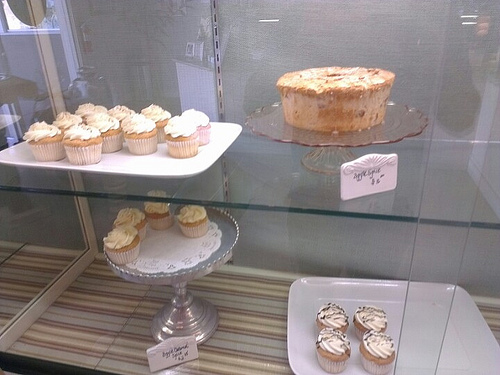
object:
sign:
[335, 157, 401, 200]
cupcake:
[163, 121, 198, 153]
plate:
[106, 154, 194, 179]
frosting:
[67, 128, 100, 141]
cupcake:
[64, 143, 100, 163]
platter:
[132, 232, 241, 274]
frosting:
[181, 208, 205, 220]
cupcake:
[182, 222, 209, 237]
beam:
[212, 4, 228, 124]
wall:
[104, 3, 333, 67]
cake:
[286, 74, 381, 130]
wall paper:
[62, 290, 127, 341]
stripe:
[65, 302, 95, 315]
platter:
[264, 132, 418, 150]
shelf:
[240, 157, 310, 200]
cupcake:
[30, 127, 57, 157]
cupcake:
[100, 120, 123, 149]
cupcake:
[108, 234, 136, 258]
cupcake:
[124, 212, 142, 231]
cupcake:
[319, 307, 346, 326]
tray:
[396, 293, 477, 369]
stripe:
[232, 330, 251, 340]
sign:
[145, 346, 209, 369]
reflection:
[464, 31, 494, 82]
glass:
[94, 5, 464, 40]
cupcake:
[319, 329, 354, 370]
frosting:
[323, 332, 335, 338]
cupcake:
[367, 352, 392, 371]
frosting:
[369, 338, 387, 354]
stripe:
[234, 274, 276, 282]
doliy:
[145, 234, 198, 265]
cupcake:
[149, 211, 176, 230]